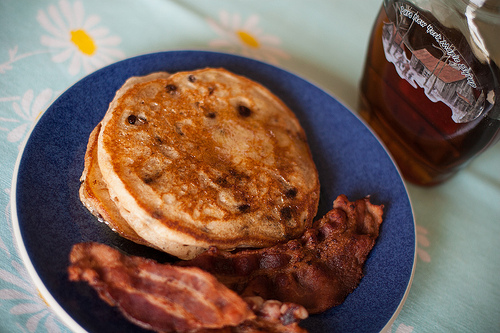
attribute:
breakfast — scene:
[10, 50, 417, 332]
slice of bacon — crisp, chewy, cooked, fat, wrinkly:
[61, 240, 312, 332]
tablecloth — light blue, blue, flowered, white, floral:
[0, 0, 498, 332]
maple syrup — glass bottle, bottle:
[358, 0, 500, 188]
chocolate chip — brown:
[235, 104, 251, 117]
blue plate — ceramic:
[7, 50, 418, 331]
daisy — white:
[32, 4, 132, 74]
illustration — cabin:
[372, 22, 486, 131]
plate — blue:
[0, 42, 422, 331]